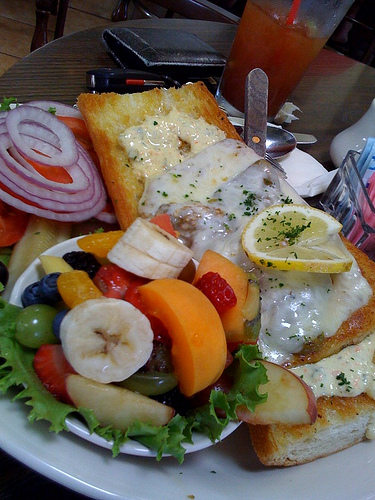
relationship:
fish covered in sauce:
[69, 71, 374, 472] [132, 131, 372, 374]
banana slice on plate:
[57, 299, 168, 387] [5, 92, 374, 494]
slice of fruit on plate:
[60, 370, 178, 440] [5, 92, 374, 494]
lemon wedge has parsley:
[238, 199, 362, 282] [273, 218, 313, 242]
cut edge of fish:
[258, 403, 373, 465] [69, 71, 374, 472]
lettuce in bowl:
[3, 299, 83, 447] [8, 222, 270, 465]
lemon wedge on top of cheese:
[238, 199, 362, 282] [195, 166, 359, 354]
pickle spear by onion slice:
[7, 210, 76, 282] [5, 96, 91, 177]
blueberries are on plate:
[15, 243, 93, 313] [5, 92, 374, 494]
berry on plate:
[190, 266, 246, 323] [5, 92, 374, 494]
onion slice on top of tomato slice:
[5, 96, 91, 177] [5, 156, 77, 243]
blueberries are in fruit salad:
[15, 243, 93, 313] [5, 217, 279, 465]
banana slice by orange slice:
[57, 299, 168, 387] [131, 269, 244, 404]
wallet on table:
[92, 14, 250, 79] [4, 11, 373, 131]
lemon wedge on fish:
[238, 199, 362, 282] [69, 71, 374, 472]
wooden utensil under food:
[236, 56, 290, 159] [5, 87, 374, 456]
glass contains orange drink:
[205, 0, 350, 133] [211, 10, 326, 123]